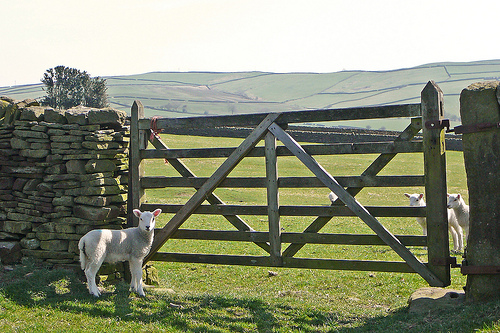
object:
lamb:
[78, 207, 162, 296]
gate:
[123, 78, 450, 287]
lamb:
[445, 191, 470, 241]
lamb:
[403, 192, 464, 253]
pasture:
[141, 118, 470, 293]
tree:
[39, 66, 112, 110]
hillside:
[0, 59, 499, 134]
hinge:
[425, 118, 498, 133]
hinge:
[433, 256, 496, 269]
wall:
[459, 81, 499, 304]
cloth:
[149, 116, 166, 141]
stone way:
[0, 79, 499, 302]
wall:
[0, 96, 130, 285]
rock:
[407, 286, 467, 314]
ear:
[152, 207, 161, 216]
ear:
[131, 207, 142, 217]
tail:
[78, 239, 87, 269]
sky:
[0, 1, 497, 58]